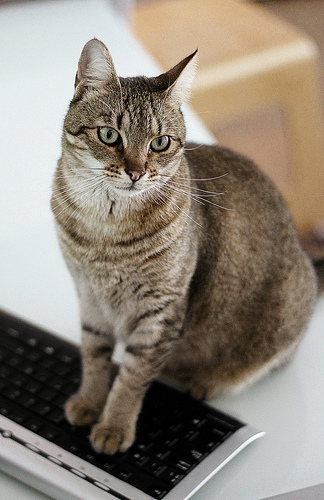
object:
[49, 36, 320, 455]
cat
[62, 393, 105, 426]
paws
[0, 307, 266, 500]
keyboard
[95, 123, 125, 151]
eyes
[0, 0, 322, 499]
desk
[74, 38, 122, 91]
ears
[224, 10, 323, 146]
floor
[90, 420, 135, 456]
paws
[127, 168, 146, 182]
nose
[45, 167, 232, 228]
whiskers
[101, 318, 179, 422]
legs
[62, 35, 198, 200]
head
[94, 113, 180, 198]
face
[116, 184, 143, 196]
mouth